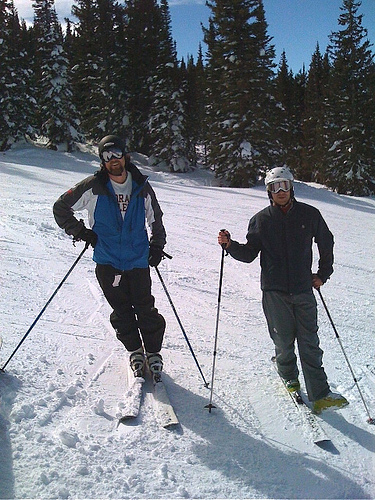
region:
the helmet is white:
[259, 160, 308, 201]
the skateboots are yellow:
[279, 373, 352, 417]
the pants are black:
[94, 282, 171, 348]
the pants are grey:
[265, 299, 329, 388]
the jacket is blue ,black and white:
[60, 181, 175, 264]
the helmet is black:
[98, 135, 132, 154]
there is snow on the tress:
[103, 66, 289, 124]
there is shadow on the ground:
[192, 392, 324, 479]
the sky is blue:
[280, 4, 324, 43]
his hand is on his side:
[51, 173, 183, 355]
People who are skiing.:
[27, 102, 367, 401]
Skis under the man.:
[93, 325, 206, 465]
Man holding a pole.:
[196, 190, 255, 438]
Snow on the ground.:
[55, 350, 165, 488]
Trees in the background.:
[101, 19, 257, 168]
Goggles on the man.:
[61, 123, 143, 172]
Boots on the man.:
[102, 298, 205, 385]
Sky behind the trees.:
[176, 16, 331, 103]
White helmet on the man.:
[260, 158, 308, 208]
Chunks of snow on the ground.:
[30, 380, 118, 482]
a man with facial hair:
[89, 128, 142, 178]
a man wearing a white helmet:
[244, 162, 303, 211]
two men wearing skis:
[21, 139, 342, 488]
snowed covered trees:
[113, 97, 282, 153]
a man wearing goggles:
[90, 135, 138, 179]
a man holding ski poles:
[27, 141, 185, 396]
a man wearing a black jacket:
[236, 171, 323, 307]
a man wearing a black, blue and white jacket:
[34, 136, 179, 288]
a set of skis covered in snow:
[108, 340, 186, 498]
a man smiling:
[89, 125, 152, 189]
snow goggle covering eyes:
[97, 144, 128, 158]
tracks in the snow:
[54, 314, 87, 383]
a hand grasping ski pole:
[204, 225, 233, 256]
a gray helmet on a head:
[263, 165, 288, 179]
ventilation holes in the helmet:
[272, 167, 289, 173]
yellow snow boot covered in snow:
[305, 396, 347, 421]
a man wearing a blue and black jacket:
[80, 128, 195, 497]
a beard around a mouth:
[107, 158, 134, 175]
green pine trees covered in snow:
[152, 85, 205, 171]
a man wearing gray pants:
[253, 162, 348, 416]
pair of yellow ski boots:
[267, 366, 370, 451]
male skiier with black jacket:
[202, 159, 373, 445]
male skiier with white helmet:
[216, 157, 372, 455]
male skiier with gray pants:
[211, 158, 373, 431]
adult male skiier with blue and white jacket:
[26, 149, 207, 455]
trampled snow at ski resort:
[21, 410, 372, 491]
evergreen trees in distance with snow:
[6, 2, 372, 128]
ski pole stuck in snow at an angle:
[9, 241, 126, 422]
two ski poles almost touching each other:
[117, 229, 271, 429]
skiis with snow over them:
[74, 321, 191, 438]